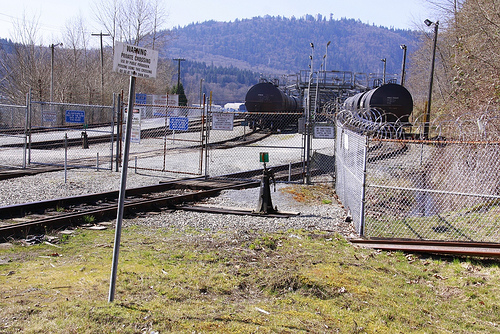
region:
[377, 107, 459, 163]
Barbed wire is on top of the fence.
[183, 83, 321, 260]
A chain link gate crosses the tracks.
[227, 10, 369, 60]
Tree covered mountains are in the background.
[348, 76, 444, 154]
The train cars have a cylinder shape.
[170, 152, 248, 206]
A wood plank is under the gate.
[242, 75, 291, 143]
The train car is black.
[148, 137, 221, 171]
Gravel covers the ground in the tracks.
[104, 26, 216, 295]
A warning sign is posted beside the tracks.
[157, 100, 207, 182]
A blue and white sign is posted on the gate.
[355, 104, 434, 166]
The top of the fence is rusted.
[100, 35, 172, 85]
white sign with black lettering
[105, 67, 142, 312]
thin metal pole supporting sign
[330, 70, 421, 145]
black tank car parked on train tracks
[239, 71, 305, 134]
black tank car parked on train tracks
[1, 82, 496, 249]
aluminum fence near train tracks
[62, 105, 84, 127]
blue sign on aluminum fence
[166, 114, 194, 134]
blue sign on aluminum fence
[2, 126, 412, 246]
brown metal train tracks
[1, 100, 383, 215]
long narrow patch of light gray gravel between train tracks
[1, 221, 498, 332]
spotty patch of green grass and mud near train tracks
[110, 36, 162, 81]
WARNING sign indicating private property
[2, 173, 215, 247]
old railroad tracks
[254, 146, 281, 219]
rail route switch with green flag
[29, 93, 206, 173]
security chain-link gate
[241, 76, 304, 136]
black oil tank railroad car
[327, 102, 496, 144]
barbed wire atop chain-link fence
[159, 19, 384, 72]
hill in the background with trees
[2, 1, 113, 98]
bare trees and electric telephone poles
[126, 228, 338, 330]
thin grass and dirt outside the station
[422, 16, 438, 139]
tall metal lamp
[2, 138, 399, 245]
a set of train tracks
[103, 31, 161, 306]
a white warning sign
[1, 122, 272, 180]
a set of railroad tracks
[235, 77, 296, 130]
a black train oil car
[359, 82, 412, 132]
a black train oil car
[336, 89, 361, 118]
a black train oil car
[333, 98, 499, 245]
a barbed wire metal fence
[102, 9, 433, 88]
a large hill in distance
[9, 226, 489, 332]
patch of green grass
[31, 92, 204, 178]
barbed wire chain link gate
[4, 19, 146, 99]
the trees without leaves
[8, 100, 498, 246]
the fence above the tracks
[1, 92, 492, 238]
the fence is metal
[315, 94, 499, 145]
the barbed wire on the fence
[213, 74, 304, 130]
the train on the tracks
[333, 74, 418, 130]
the train on the tracks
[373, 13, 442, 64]
the lights above the train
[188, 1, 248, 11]
the clear blue sky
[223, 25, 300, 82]
the trees on the mountain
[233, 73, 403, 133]
the train is black